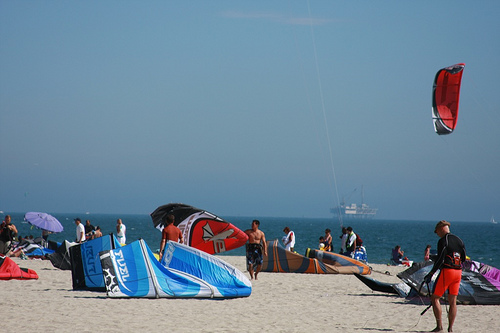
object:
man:
[243, 219, 268, 280]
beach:
[1, 256, 500, 333]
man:
[424, 220, 466, 332]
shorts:
[432, 266, 462, 299]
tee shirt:
[430, 233, 465, 275]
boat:
[489, 217, 499, 226]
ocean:
[3, 212, 500, 269]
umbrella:
[24, 211, 64, 233]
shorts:
[247, 244, 263, 265]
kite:
[428, 62, 465, 137]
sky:
[1, 1, 500, 224]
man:
[74, 217, 87, 243]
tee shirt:
[76, 223, 85, 240]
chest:
[249, 231, 261, 244]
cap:
[435, 219, 451, 232]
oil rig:
[329, 183, 378, 221]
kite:
[1, 252, 38, 280]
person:
[392, 243, 407, 263]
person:
[42, 227, 50, 242]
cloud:
[221, 12, 329, 28]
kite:
[99, 240, 253, 298]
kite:
[69, 235, 124, 290]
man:
[340, 226, 349, 254]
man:
[158, 214, 185, 256]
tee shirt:
[163, 224, 182, 243]